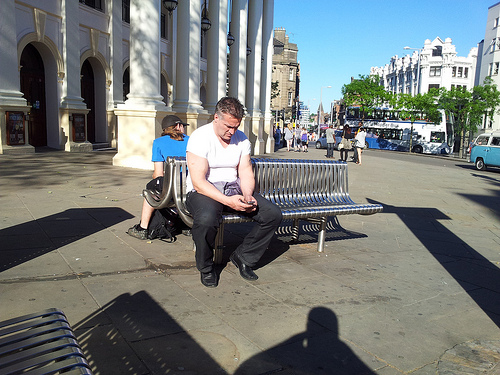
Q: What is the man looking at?
A: Phone.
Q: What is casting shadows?
A: The sun.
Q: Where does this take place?
A: Downtown.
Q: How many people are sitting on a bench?
A: Two.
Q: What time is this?
A: Daytime.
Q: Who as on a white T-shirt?
A: A man.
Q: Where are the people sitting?
A: Bench.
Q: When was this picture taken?
A: Afternoon.